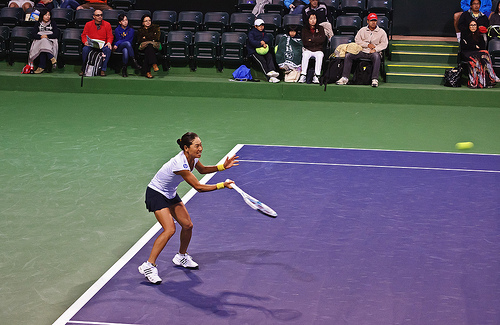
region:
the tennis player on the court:
[137, 120, 281, 286]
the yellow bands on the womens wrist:
[214, 158, 228, 195]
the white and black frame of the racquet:
[225, 178, 281, 220]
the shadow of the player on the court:
[158, 273, 306, 324]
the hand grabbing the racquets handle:
[225, 177, 238, 190]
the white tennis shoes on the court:
[137, 252, 202, 287]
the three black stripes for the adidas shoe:
[143, 263, 153, 278]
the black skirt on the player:
[136, 183, 188, 216]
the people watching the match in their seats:
[27, 7, 387, 89]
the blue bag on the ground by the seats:
[228, 63, 256, 80]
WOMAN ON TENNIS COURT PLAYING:
[100, 92, 244, 278]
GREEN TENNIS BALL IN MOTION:
[457, 122, 489, 153]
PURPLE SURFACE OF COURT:
[149, 110, 445, 315]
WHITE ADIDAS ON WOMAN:
[97, 242, 218, 289]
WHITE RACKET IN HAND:
[216, 175, 296, 226]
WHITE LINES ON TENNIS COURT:
[49, 207, 136, 320]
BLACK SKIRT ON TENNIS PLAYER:
[143, 153, 215, 233]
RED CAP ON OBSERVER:
[359, 14, 386, 23]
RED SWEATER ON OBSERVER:
[77, 25, 134, 52]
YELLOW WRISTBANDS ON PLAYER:
[209, 146, 234, 197]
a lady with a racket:
[133, 99, 298, 302]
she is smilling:
[124, 90, 326, 314]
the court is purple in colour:
[227, 95, 497, 322]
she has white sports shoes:
[127, 237, 252, 288]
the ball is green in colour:
[429, 134, 499, 154]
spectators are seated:
[8, 12, 418, 84]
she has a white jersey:
[137, 154, 195, 194]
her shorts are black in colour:
[140, 185, 186, 207]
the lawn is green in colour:
[38, 97, 139, 277]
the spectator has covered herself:
[276, 24, 300, 79]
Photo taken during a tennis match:
[14, 9, 490, 314]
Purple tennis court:
[149, 109, 496, 319]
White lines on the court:
[76, 135, 243, 304]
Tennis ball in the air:
[434, 129, 489, 157]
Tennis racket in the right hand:
[219, 172, 296, 231]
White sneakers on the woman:
[125, 249, 218, 286]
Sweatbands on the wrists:
[212, 154, 227, 199]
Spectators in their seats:
[14, 14, 487, 92]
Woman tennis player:
[123, 118, 261, 298]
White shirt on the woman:
[144, 149, 210, 202]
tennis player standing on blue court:
[128, 125, 270, 284]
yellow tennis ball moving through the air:
[451, 132, 473, 152]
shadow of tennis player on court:
[131, 232, 288, 324]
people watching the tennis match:
[9, 3, 499, 98]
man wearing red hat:
[333, 12, 385, 83]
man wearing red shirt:
[78, 12, 109, 72]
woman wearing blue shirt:
[113, 7, 140, 69]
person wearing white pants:
[297, 12, 328, 79]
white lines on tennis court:
[55, 138, 499, 324]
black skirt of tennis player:
[136, 189, 182, 209]